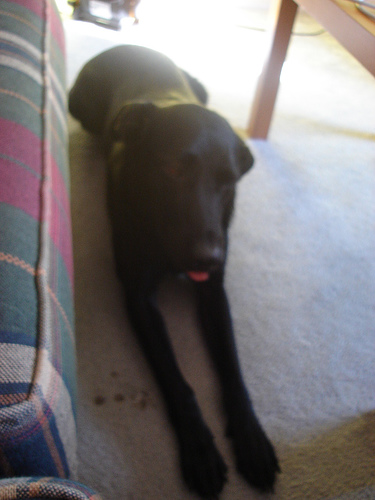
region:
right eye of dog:
[213, 160, 239, 197]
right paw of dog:
[240, 442, 267, 484]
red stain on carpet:
[91, 390, 106, 407]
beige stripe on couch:
[6, 356, 25, 373]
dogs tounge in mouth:
[191, 270, 206, 280]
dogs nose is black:
[191, 253, 223, 268]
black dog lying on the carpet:
[60, 35, 295, 498]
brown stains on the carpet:
[89, 361, 152, 416]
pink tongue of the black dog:
[185, 267, 217, 285]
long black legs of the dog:
[127, 282, 278, 489]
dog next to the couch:
[1, 7, 288, 496]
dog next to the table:
[70, 0, 373, 499]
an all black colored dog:
[68, 34, 280, 496]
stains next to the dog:
[92, 365, 157, 415]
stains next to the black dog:
[93, 363, 154, 413]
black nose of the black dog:
[187, 241, 225, 263]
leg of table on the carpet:
[243, 1, 373, 142]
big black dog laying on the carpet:
[67, 42, 285, 497]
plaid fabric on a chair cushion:
[0, 0, 100, 498]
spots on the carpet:
[90, 369, 151, 410]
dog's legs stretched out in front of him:
[119, 289, 282, 499]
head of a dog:
[104, 100, 254, 292]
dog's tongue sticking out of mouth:
[181, 265, 217, 286]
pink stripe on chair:
[0, 118, 41, 216]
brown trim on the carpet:
[76, 298, 373, 499]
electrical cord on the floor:
[230, 25, 328, 37]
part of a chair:
[77, 385, 84, 412]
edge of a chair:
[64, 427, 70, 453]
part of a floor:
[188, 463, 193, 482]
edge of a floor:
[304, 344, 306, 361]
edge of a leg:
[246, 453, 252, 458]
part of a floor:
[289, 367, 295, 394]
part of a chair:
[75, 404, 87, 423]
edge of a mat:
[277, 367, 289, 411]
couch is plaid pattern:
[3, 68, 72, 368]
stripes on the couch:
[6, 219, 67, 447]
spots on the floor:
[84, 358, 152, 463]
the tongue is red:
[192, 269, 210, 280]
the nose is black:
[204, 241, 228, 262]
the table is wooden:
[259, 0, 366, 141]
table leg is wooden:
[251, 4, 293, 145]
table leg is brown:
[245, 6, 291, 142]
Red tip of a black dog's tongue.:
[185, 270, 208, 281]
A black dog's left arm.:
[195, 283, 281, 494]